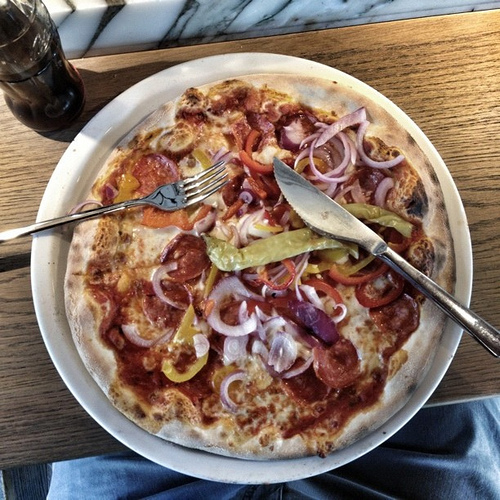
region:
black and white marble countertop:
[62, 0, 498, 60]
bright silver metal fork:
[1, 159, 234, 249]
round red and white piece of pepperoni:
[309, 335, 364, 387]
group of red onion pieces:
[296, 111, 399, 194]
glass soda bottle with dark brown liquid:
[0, 0, 89, 135]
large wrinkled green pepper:
[202, 225, 362, 271]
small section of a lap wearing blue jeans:
[41, 402, 498, 496]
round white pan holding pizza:
[28, 52, 476, 487]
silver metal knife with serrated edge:
[271, 147, 498, 356]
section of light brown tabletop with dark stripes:
[385, 25, 494, 97]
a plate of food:
[19, 12, 481, 458]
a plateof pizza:
[4, 69, 496, 466]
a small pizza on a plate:
[11, 86, 492, 459]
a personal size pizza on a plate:
[32, 51, 496, 458]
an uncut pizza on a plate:
[23, 51, 489, 441]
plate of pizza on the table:
[16, 58, 492, 448]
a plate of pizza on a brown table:
[4, 12, 496, 462]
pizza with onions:
[46, 5, 494, 407]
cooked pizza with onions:
[79, 44, 496, 448]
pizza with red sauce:
[25, 98, 487, 441]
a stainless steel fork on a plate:
[2, 152, 227, 242]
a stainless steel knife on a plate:
[273, 158, 498, 358]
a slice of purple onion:
[207, 277, 264, 334]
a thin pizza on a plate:
[66, 73, 460, 457]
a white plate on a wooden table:
[21, 52, 474, 486]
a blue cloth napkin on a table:
[6, 395, 497, 495]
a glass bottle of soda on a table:
[3, 0, 83, 142]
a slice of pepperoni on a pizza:
[312, 337, 358, 389]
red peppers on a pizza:
[241, 129, 294, 193]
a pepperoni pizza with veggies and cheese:
[67, 53, 457, 461]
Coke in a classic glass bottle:
[1, 0, 88, 137]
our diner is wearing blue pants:
[37, 393, 499, 498]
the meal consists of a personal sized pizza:
[62, 71, 458, 463]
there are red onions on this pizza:
[201, 273, 308, 415]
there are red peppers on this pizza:
[256, 253, 406, 310]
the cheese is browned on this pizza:
[152, 380, 327, 462]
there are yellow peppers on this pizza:
[158, 266, 220, 383]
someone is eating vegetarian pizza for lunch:
[61, 70, 456, 464]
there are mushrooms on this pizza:
[156, 86, 211, 156]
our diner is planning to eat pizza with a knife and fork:
[1, 50, 475, 487]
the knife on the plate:
[272, 156, 499, 355]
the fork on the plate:
[1, 159, 229, 250]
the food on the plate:
[62, 72, 455, 461]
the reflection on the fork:
[0, 227, 30, 240]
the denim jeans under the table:
[46, 396, 498, 499]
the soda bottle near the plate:
[0, 2, 85, 132]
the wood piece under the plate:
[0, 7, 498, 469]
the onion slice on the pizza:
[206, 276, 258, 333]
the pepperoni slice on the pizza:
[312, 337, 359, 386]